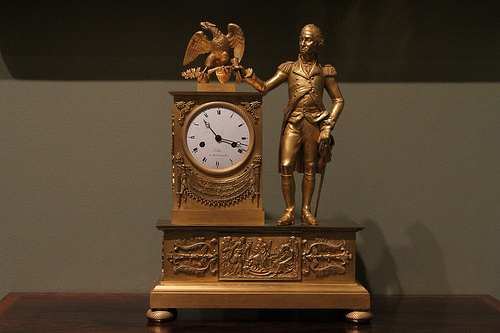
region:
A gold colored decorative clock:
[128, 20, 394, 324]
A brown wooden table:
[4, 279, 487, 324]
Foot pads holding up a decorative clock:
[140, 304, 183, 328]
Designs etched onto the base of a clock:
[144, 210, 369, 309]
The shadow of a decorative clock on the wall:
[348, 208, 466, 316]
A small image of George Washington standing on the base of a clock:
[259, 16, 362, 224]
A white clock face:
[166, 94, 265, 189]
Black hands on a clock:
[192, 106, 258, 170]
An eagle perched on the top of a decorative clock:
[177, 19, 280, 95]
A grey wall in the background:
[36, 108, 153, 214]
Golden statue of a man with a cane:
[267, 22, 345, 230]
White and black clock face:
[183, 101, 254, 176]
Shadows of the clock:
[329, 198, 461, 320]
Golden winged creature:
[177, 10, 251, 83]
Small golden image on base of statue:
[216, 237, 304, 282]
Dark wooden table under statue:
[15, 290, 487, 332]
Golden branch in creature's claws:
[177, 60, 244, 86]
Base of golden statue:
[139, 280, 379, 326]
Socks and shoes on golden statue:
[272, 167, 321, 229]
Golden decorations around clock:
[167, 155, 272, 216]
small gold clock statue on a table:
[144, 15, 373, 321]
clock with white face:
[180, 103, 253, 175]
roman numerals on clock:
[179, 100, 253, 175]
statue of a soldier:
[242, 21, 354, 226]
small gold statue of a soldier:
[246, 23, 343, 227]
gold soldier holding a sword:
[246, 22, 347, 226]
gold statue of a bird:
[181, 19, 246, 84]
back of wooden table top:
[1, 290, 498, 329]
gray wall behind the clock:
[6, 82, 151, 285]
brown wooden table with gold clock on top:
[0, 290, 498, 332]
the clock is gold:
[140, 10, 374, 325]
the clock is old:
[144, 16, 380, 323]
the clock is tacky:
[143, 9, 374, 327]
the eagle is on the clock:
[180, 15, 253, 90]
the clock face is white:
[185, 105, 251, 173]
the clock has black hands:
[199, 117, 251, 153]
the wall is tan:
[0, 1, 498, 311]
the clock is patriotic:
[146, 0, 376, 326]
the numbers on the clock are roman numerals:
[186, 104, 251, 171]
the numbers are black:
[181, 98, 257, 177]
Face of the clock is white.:
[181, 100, 255, 172]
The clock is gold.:
[138, 17, 373, 328]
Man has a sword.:
[309, 130, 338, 230]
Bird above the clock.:
[179, 15, 258, 80]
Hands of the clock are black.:
[198, 116, 250, 163]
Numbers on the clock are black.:
[191, 108, 250, 168]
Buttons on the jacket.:
[282, 72, 329, 112]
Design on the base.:
[163, 232, 348, 287]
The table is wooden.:
[24, 294, 144, 331]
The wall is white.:
[21, 99, 148, 237]